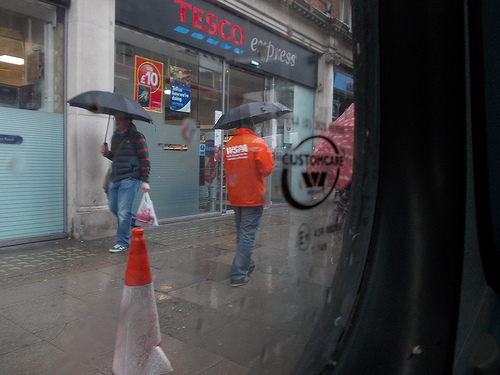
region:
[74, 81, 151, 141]
black umbrella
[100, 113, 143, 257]
a person walking down the sidewalk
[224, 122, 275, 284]
a person walking down the sidewalk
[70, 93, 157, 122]
a black umbrella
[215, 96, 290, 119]
a black umbrella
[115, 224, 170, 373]
an orange and white cone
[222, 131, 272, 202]
an orange jacket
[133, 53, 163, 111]
a sign in the window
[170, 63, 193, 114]
a sign in the window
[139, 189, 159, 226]
a red and white bag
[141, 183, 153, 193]
the hand of a person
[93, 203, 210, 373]
Orange cone on a sidewalk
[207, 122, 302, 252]
Orange jacket on a man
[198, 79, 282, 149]
Black umbrella over a man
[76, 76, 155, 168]
Man holding an umbrella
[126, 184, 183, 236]
Bag in a hand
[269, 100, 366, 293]
Sign on a window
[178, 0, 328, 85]
Sign on a building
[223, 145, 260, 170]
White sign on a jacket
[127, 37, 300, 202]
Glass wall on a store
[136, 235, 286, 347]
Gray cement sidewalk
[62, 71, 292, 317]
Two people walking with umbrellas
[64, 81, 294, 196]
Two black umbrellas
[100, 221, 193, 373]
A white cone with orange top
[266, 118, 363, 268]
CustomCare sticker on window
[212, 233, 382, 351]
Drops of water on window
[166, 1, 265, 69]
Red lettering spells Tesco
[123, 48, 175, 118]
A red sign with white lettering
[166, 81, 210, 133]
A blue and white sign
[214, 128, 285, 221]
Orange jacket worn by man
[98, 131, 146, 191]
Gray vest worn by man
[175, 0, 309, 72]
the name of a store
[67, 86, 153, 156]
a black umbrella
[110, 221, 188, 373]
a tall orange and white cone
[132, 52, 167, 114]
a poster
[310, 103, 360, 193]
part of a red and white umbrella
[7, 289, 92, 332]
a section of a concrete sidewalk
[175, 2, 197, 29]
a red capital letter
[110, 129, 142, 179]
a man's gray vest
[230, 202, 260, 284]
men's blue jean pants